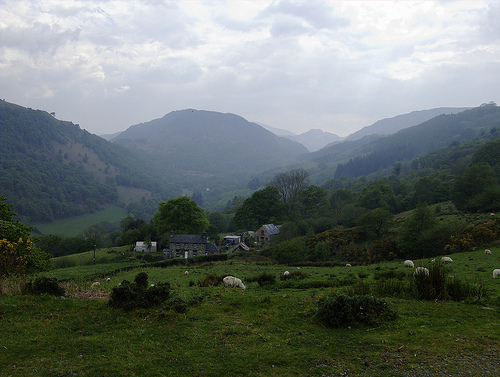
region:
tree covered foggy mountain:
[114, 84, 317, 195]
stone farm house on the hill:
[154, 223, 251, 273]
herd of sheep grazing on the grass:
[214, 257, 473, 311]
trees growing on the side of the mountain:
[246, 142, 466, 214]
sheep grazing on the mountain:
[213, 251, 474, 325]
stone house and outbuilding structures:
[120, 207, 287, 264]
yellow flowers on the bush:
[2, 228, 47, 299]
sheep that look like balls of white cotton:
[216, 236, 486, 308]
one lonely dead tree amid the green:
[269, 167, 314, 230]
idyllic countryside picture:
[96, 181, 436, 303]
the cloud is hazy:
[305, 154, 320, 168]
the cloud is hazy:
[290, 53, 335, 83]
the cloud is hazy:
[308, 133, 335, 162]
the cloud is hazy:
[262, 62, 306, 101]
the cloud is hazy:
[331, 131, 371, 156]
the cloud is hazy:
[353, 111, 381, 138]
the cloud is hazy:
[234, 177, 276, 199]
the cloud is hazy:
[216, 185, 233, 195]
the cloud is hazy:
[202, 184, 246, 204]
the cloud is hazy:
[201, 191, 245, 201]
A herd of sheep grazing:
[90, 246, 498, 313]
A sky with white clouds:
[10, 2, 470, 111]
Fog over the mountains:
[10, 55, 497, 208]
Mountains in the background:
[2, 73, 488, 224]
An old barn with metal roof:
[250, 220, 286, 255]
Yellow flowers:
[0, 220, 50, 295]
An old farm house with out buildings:
[127, 218, 279, 264]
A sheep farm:
[18, 126, 496, 354]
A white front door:
[179, 248, 194, 264]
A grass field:
[10, 299, 487, 371]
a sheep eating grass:
[218, 270, 247, 290]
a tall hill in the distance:
[110, 97, 319, 185]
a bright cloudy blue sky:
[8, 6, 489, 123]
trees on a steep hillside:
[8, 143, 111, 219]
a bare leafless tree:
[269, 160, 314, 214]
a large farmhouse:
[169, 226, 212, 259]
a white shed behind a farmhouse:
[129, 236, 159, 254]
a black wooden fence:
[65, 248, 228, 285]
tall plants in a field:
[398, 257, 483, 299]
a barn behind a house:
[252, 219, 278, 246]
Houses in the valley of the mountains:
[112, 201, 305, 266]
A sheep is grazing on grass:
[220, 271, 248, 300]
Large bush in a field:
[306, 289, 410, 335]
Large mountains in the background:
[100, 80, 469, 190]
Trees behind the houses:
[112, 192, 217, 241]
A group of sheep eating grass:
[392, 244, 490, 286]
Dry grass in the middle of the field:
[65, 282, 110, 317]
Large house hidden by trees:
[247, 214, 311, 274]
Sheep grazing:
[85, 270, 157, 302]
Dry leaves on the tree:
[3, 236, 49, 276]